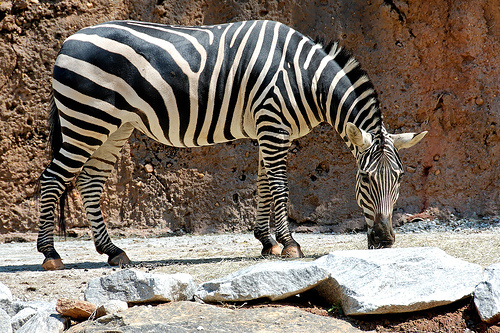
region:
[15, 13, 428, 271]
The zebra shown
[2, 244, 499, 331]
The rocks in front of the zebra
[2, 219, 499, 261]
The dirt the zebra is on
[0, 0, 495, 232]
The stone wall in the back ground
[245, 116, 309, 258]
The front legs of the zebra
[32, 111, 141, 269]
The back legs of the zebra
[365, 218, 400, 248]
The nose of the zebra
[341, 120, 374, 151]
The left ear of the zebra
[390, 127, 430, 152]
The right ear of the zebra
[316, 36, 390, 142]
The mane of the zebra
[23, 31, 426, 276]
Zebra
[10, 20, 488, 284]
Zebra standing in front of a red rock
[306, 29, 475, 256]
Zebra leaning down to eat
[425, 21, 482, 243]
Red rock wall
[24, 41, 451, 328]
Zebra behind rocks on the ground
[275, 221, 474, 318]
Rocks on the ground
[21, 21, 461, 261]
Black and white striped zebra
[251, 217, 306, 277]
Front hooves of a zebra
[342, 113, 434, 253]
A zebra with white ears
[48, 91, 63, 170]
Tail of a zebra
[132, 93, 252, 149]
Round belly of zebra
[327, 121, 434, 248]
Zebra with his head down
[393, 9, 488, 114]
Red clay rock wall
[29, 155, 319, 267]
Zebra's four legs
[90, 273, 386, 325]
Uneven rocks on ground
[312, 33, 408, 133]
Stripped mane on zebra's neck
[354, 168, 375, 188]
Black eye of zebra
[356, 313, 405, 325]
Shadow of rock on ground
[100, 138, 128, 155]
White spot on zebra's leg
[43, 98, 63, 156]
black tail on zebra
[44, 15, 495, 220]
Zebra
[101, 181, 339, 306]
Rocks in front of the zebra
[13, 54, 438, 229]
Zebra at the zoo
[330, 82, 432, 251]
Zebra eating some grass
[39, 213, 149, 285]
Zebra hooves on the ground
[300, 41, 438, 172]
Zebra mane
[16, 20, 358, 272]
The zebra in the enclosure at the zoo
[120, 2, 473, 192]
Rock wall enclosure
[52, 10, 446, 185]
Black and white stripes on the zebra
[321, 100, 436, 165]
Zebra ears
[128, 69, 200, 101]
black stripes on a zebra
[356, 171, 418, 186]
eyes in a face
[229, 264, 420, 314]
large rocks on the ground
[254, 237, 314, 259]
hooves supporting the legs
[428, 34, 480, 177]
a stone wall behind the zebra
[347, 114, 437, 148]
two points ears on a head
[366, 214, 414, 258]
a black snout on the face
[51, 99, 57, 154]
a long silky black hair on a tail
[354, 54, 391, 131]
a black and white spiny mane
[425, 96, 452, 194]
small holes in the stone wall